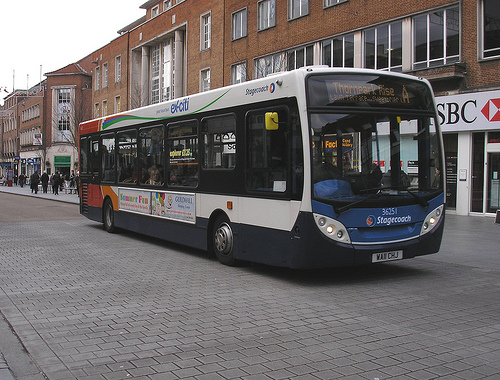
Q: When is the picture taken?
A: Day time.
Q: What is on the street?
A: A bus.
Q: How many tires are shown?
A: Two.